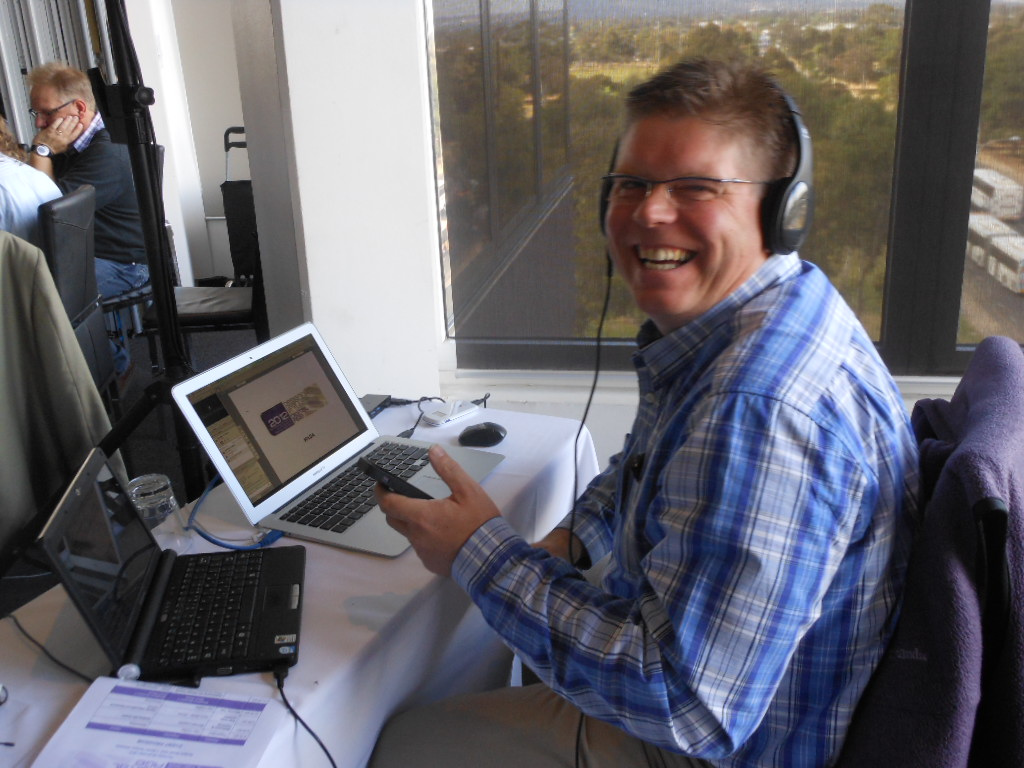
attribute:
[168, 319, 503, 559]
laptop — silver, white 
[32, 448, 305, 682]
laptop — black 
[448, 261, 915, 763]
shirt — blue, plaid patterned, blue and white, plaid 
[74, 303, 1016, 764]
furniture — some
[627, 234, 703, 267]
smile — laughing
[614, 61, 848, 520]
man — one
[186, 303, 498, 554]
laptop — silver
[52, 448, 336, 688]
laptop — black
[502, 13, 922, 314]
trees — some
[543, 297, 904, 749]
shirt — blue, gray, striped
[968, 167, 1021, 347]
cars — train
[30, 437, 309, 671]
laptop — black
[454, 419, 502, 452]
mouse — black